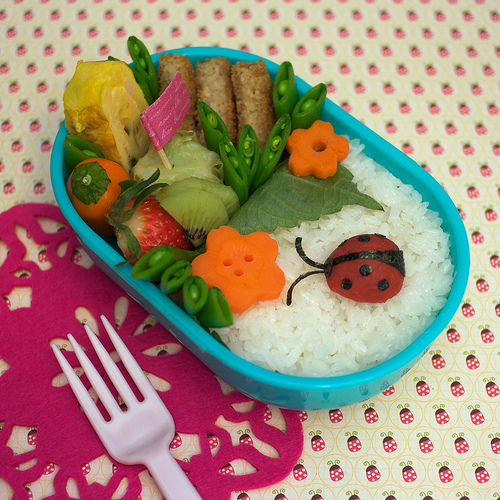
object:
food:
[63, 35, 456, 377]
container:
[50, 46, 471, 410]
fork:
[50, 315, 206, 498]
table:
[1, 3, 499, 500]